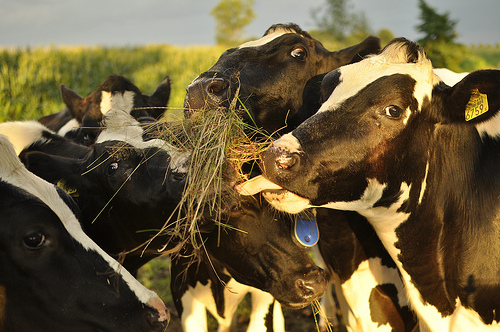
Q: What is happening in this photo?
A: Cows are eating.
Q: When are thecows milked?
A: Every morning.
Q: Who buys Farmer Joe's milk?
A: A local dairy.